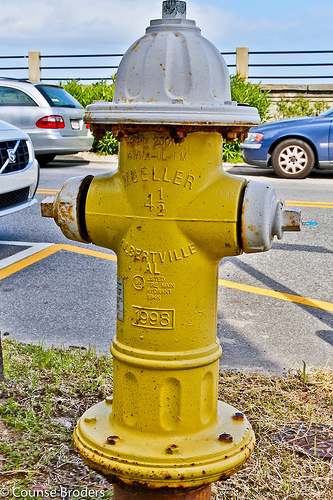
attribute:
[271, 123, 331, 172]
car — blue, silver, parked, tan, here, gray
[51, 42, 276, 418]
fire hydrant — marked, stamped, yellow, white, rusty, here, metallic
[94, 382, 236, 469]
bolts — rusty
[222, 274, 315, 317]
lines — yellow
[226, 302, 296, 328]
road — tarmacked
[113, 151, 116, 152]
grass — green, short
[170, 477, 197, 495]
plate — metal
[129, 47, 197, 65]
lid — white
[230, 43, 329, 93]
fence — here, concrete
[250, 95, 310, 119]
shrubbery — growing